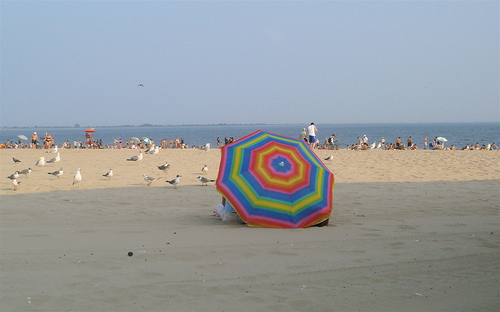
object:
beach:
[0, 129, 499, 310]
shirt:
[224, 198, 237, 212]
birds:
[43, 152, 62, 165]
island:
[0, 122, 266, 131]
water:
[0, 121, 500, 147]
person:
[213, 195, 246, 226]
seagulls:
[0, 143, 334, 218]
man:
[29, 132, 39, 149]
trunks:
[28, 142, 32, 147]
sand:
[0, 144, 498, 309]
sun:
[0, 149, 500, 200]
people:
[0, 121, 499, 150]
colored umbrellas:
[215, 129, 335, 230]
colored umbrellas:
[83, 128, 94, 133]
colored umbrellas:
[436, 137, 447, 142]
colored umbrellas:
[141, 136, 152, 145]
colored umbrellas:
[17, 135, 28, 141]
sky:
[0, 0, 500, 138]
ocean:
[0, 120, 500, 147]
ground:
[0, 150, 500, 259]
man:
[304, 122, 318, 150]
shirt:
[307, 125, 316, 137]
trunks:
[307, 134, 315, 150]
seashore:
[1, 134, 498, 149]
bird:
[101, 167, 115, 178]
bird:
[70, 167, 82, 185]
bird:
[45, 166, 65, 179]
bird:
[126, 151, 143, 162]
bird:
[165, 174, 183, 187]